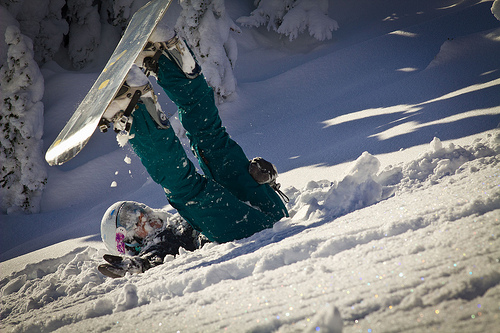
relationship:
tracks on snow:
[0, 195, 500, 333] [288, 101, 429, 216]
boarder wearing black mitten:
[96, 4, 290, 277] [97, 253, 152, 278]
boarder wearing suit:
[96, 4, 290, 277] [116, 89, 291, 238]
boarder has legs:
[96, 4, 290, 277] [124, 73, 269, 228]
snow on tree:
[0, 0, 500, 333] [7, 27, 64, 202]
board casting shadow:
[44, 0, 172, 168] [162, 145, 404, 279]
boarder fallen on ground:
[96, 4, 290, 277] [3, 30, 498, 328]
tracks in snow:
[0, 195, 500, 333] [297, 58, 494, 330]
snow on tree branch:
[0, 0, 500, 333] [172, 0, 244, 106]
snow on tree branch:
[0, 0, 500, 333] [239, 1, 339, 41]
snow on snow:
[0, 0, 500, 333] [0, 0, 500, 333]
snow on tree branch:
[0, 0, 500, 333] [19, 5, 100, 74]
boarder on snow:
[96, 4, 290, 277] [10, 10, 498, 331]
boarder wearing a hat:
[96, 4, 290, 277] [97, 191, 166, 262]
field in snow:
[18, 158, 488, 310] [237, 255, 328, 294]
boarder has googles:
[96, 4, 290, 277] [100, 194, 157, 247]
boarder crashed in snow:
[96, 4, 290, 277] [10, 10, 498, 331]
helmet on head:
[100, 200, 166, 256] [88, 196, 185, 264]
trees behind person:
[2, 9, 362, 206] [87, 48, 295, 273]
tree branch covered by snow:
[233, 0, 346, 44] [257, 8, 326, 38]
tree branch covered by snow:
[5, 29, 54, 218] [10, 10, 498, 331]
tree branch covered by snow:
[20, 10, 71, 82] [19, 9, 41, 31]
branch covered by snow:
[175, 0, 245, 104] [10, 10, 498, 331]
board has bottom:
[44, 0, 172, 168] [45, 0, 162, 167]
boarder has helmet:
[96, 4, 290, 277] [96, 195, 140, 250]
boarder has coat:
[96, 4, 290, 277] [133, 198, 214, 273]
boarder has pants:
[75, 49, 297, 274] [117, 63, 301, 246]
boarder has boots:
[96, 4, 290, 277] [95, 81, 165, 136]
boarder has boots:
[96, 4, 290, 277] [137, 44, 187, 81]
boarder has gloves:
[96, 4, 290, 277] [97, 157, 277, 277]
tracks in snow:
[49, 211, 452, 291] [10, 10, 498, 331]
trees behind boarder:
[0, 0, 500, 216] [79, 57, 287, 278]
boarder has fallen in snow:
[96, 4, 290, 277] [303, 166, 487, 284]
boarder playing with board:
[96, 4, 290, 277] [44, 0, 172, 168]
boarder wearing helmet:
[96, 4, 290, 277] [73, 185, 166, 252]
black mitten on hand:
[98, 247, 161, 286] [89, 244, 170, 285]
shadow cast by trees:
[261, 55, 499, 168] [2, 9, 362, 206]